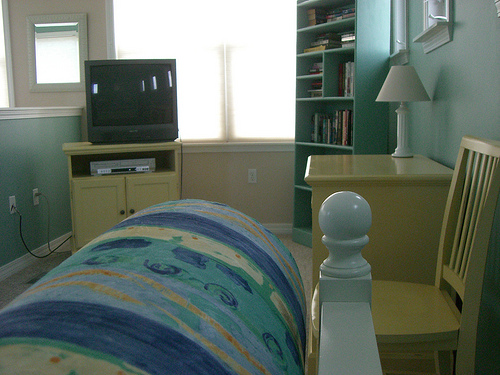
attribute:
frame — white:
[29, 13, 88, 92]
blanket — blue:
[3, 200, 305, 371]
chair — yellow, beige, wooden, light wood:
[312, 138, 499, 370]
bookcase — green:
[294, 0, 391, 248]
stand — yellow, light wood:
[64, 139, 182, 246]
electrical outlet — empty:
[248, 168, 260, 185]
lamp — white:
[373, 63, 432, 159]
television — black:
[84, 58, 177, 143]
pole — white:
[321, 192, 371, 303]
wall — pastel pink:
[188, 150, 292, 217]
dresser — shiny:
[306, 152, 461, 283]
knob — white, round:
[320, 192, 371, 255]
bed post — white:
[315, 191, 381, 374]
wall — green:
[0, 119, 88, 265]